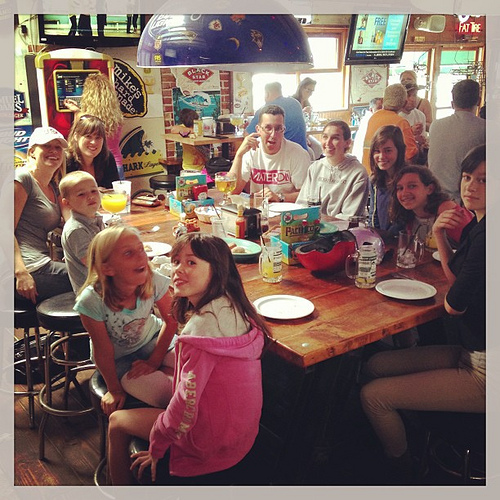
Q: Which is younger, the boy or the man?
A: The boy is younger than the man.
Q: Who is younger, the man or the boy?
A: The boy is younger than the man.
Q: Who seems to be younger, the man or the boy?
A: The boy is younger than the man.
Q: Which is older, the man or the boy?
A: The man is older than the boy.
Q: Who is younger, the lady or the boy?
A: The boy is younger than the lady.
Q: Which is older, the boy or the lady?
A: The lady is older than the boy.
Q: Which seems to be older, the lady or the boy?
A: The lady is older than the boy.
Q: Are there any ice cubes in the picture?
A: No, there are no ice cubes.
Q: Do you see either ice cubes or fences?
A: No, there are no ice cubes or fences.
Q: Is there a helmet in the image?
A: Yes, there is a helmet.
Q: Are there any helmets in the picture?
A: Yes, there is a helmet.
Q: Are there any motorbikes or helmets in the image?
A: Yes, there is a helmet.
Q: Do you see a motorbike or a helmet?
A: Yes, there is a helmet.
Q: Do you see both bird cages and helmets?
A: No, there is a helmet but no bird cages.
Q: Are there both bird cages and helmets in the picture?
A: No, there is a helmet but no bird cages.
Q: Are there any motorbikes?
A: No, there are no motorbikes.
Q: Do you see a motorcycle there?
A: No, there are no motorcycles.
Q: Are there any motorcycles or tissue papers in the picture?
A: No, there are no motorcycles or tissue papers.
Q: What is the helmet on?
A: The helmet is on the table.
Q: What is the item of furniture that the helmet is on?
A: The piece of furniture is a table.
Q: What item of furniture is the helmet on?
A: The helmet is on the table.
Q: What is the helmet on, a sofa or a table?
A: The helmet is on a table.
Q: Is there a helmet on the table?
A: Yes, there is a helmet on the table.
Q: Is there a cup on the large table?
A: No, there is a helmet on the table.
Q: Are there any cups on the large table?
A: No, there is a helmet on the table.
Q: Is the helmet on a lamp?
A: No, the helmet is on the table.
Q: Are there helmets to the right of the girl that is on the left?
A: Yes, there is a helmet to the right of the girl.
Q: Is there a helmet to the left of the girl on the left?
A: No, the helmet is to the right of the girl.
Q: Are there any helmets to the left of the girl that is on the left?
A: No, the helmet is to the right of the girl.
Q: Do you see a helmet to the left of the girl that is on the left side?
A: No, the helmet is to the right of the girl.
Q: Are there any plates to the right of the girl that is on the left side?
A: No, there is a helmet to the right of the girl.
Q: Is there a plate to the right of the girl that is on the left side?
A: No, there is a helmet to the right of the girl.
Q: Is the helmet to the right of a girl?
A: Yes, the helmet is to the right of a girl.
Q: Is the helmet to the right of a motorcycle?
A: No, the helmet is to the right of a girl.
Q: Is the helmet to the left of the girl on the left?
A: No, the helmet is to the right of the girl.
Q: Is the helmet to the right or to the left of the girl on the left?
A: The helmet is to the right of the girl.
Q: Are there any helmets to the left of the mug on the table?
A: Yes, there is a helmet to the left of the mug.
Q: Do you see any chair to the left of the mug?
A: No, there is a helmet to the left of the mug.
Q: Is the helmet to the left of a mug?
A: Yes, the helmet is to the left of a mug.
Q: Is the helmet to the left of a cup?
A: No, the helmet is to the left of a mug.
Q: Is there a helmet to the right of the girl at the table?
A: Yes, there is a helmet to the right of the girl.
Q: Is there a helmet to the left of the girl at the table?
A: No, the helmet is to the right of the girl.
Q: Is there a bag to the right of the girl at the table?
A: No, there is a helmet to the right of the girl.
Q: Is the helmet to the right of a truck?
A: No, the helmet is to the right of a girl.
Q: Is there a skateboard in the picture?
A: No, there are no skateboards.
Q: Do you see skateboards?
A: No, there are no skateboards.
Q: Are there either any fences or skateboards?
A: No, there are no skateboards or fences.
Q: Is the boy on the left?
A: Yes, the boy is on the left of the image.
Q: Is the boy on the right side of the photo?
A: No, the boy is on the left of the image.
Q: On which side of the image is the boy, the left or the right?
A: The boy is on the left of the image.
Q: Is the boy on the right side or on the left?
A: The boy is on the left of the image.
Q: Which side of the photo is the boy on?
A: The boy is on the left of the image.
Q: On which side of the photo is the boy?
A: The boy is on the left of the image.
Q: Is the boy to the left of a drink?
A: Yes, the boy is to the left of a drink.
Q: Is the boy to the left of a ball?
A: No, the boy is to the left of a drink.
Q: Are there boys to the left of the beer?
A: Yes, there is a boy to the left of the beer.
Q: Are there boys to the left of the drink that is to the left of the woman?
A: Yes, there is a boy to the left of the beer.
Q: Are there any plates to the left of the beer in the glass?
A: No, there is a boy to the left of the beer.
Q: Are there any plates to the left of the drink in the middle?
A: No, there is a boy to the left of the beer.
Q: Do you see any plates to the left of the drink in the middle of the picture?
A: No, there is a boy to the left of the beer.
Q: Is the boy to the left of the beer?
A: Yes, the boy is to the left of the beer.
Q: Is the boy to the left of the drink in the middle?
A: Yes, the boy is to the left of the beer.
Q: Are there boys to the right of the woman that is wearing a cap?
A: Yes, there is a boy to the right of the woman.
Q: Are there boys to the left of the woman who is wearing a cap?
A: No, the boy is to the right of the woman.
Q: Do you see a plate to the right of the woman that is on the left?
A: No, there is a boy to the right of the woman.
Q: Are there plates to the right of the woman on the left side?
A: No, there is a boy to the right of the woman.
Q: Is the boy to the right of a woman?
A: Yes, the boy is to the right of a woman.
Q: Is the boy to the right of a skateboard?
A: No, the boy is to the right of a woman.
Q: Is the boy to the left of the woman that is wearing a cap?
A: No, the boy is to the right of the woman.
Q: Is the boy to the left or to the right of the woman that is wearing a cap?
A: The boy is to the right of the woman.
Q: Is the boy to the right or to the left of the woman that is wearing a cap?
A: The boy is to the right of the woman.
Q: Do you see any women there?
A: Yes, there is a woman.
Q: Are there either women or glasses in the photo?
A: Yes, there is a woman.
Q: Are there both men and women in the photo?
A: Yes, there are both a woman and a man.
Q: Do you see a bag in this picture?
A: No, there are no bags.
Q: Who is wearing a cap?
A: The woman is wearing a cap.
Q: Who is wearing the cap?
A: The woman is wearing a cap.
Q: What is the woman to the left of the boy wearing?
A: The woman is wearing a cap.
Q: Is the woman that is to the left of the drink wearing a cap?
A: Yes, the woman is wearing a cap.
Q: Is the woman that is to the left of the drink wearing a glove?
A: No, the woman is wearing a cap.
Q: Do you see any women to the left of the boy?
A: Yes, there is a woman to the left of the boy.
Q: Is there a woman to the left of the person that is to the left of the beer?
A: Yes, there is a woman to the left of the boy.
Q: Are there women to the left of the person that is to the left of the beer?
A: Yes, there is a woman to the left of the boy.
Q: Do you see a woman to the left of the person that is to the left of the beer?
A: Yes, there is a woman to the left of the boy.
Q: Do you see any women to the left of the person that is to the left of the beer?
A: Yes, there is a woman to the left of the boy.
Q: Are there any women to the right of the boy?
A: No, the woman is to the left of the boy.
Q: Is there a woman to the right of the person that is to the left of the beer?
A: No, the woman is to the left of the boy.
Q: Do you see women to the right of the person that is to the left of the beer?
A: No, the woman is to the left of the boy.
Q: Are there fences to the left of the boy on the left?
A: No, there is a woman to the left of the boy.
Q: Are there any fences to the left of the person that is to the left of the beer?
A: No, there is a woman to the left of the boy.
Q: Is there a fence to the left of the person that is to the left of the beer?
A: No, there is a woman to the left of the boy.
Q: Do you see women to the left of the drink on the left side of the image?
A: Yes, there is a woman to the left of the drink.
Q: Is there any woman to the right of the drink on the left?
A: No, the woman is to the left of the drink.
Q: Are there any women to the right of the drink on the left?
A: No, the woman is to the left of the drink.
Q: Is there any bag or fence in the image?
A: No, there are no fences or bags.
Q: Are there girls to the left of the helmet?
A: Yes, there is a girl to the left of the helmet.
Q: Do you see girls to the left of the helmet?
A: Yes, there is a girl to the left of the helmet.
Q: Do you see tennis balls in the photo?
A: No, there are no tennis balls.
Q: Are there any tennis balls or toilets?
A: No, there are no tennis balls or toilets.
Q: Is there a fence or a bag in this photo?
A: No, there are no fences or bags.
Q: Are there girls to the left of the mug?
A: Yes, there is a girl to the left of the mug.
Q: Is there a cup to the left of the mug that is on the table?
A: No, there is a girl to the left of the mug.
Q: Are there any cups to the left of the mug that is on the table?
A: No, there is a girl to the left of the mug.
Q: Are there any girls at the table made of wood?
A: Yes, there is a girl at the table.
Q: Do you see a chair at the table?
A: No, there is a girl at the table.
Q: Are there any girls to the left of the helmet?
A: Yes, there is a girl to the left of the helmet.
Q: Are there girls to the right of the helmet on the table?
A: No, the girl is to the left of the helmet.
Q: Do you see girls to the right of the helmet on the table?
A: No, the girl is to the left of the helmet.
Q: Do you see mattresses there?
A: No, there are no mattresses.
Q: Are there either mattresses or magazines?
A: No, there are no mattresses or magazines.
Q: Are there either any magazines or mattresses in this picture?
A: No, there are no mattresses or magazines.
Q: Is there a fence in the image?
A: No, there are no fences.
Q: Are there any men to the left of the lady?
A: Yes, there is a man to the left of the lady.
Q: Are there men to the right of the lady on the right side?
A: No, the man is to the left of the lady.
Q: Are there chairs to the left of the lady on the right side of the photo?
A: No, there is a man to the left of the lady.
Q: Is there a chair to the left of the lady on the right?
A: No, there is a man to the left of the lady.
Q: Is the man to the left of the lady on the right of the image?
A: Yes, the man is to the left of the lady.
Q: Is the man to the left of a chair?
A: No, the man is to the left of the lady.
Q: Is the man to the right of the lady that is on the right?
A: No, the man is to the left of the lady.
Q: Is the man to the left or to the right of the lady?
A: The man is to the left of the lady.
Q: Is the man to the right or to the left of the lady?
A: The man is to the left of the lady.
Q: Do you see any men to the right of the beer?
A: Yes, there is a man to the right of the beer.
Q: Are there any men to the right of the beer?
A: Yes, there is a man to the right of the beer.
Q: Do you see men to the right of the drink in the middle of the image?
A: Yes, there is a man to the right of the beer.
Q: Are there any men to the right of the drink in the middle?
A: Yes, there is a man to the right of the beer.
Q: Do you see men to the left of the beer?
A: No, the man is to the right of the beer.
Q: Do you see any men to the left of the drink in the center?
A: No, the man is to the right of the beer.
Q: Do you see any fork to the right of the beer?
A: No, there is a man to the right of the beer.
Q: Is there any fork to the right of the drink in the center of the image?
A: No, there is a man to the right of the beer.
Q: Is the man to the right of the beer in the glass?
A: Yes, the man is to the right of the beer.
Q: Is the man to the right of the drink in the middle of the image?
A: Yes, the man is to the right of the beer.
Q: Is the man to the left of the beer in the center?
A: No, the man is to the right of the beer.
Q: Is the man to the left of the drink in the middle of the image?
A: No, the man is to the right of the beer.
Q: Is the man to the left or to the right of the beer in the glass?
A: The man is to the right of the beer.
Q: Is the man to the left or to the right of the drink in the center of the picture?
A: The man is to the right of the beer.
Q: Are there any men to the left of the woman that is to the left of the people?
A: Yes, there is a man to the left of the woman.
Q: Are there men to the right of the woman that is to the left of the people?
A: No, the man is to the left of the woman.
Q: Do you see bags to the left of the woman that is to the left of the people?
A: No, there is a man to the left of the woman.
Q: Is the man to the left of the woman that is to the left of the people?
A: Yes, the man is to the left of the woman.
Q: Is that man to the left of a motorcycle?
A: No, the man is to the left of the woman.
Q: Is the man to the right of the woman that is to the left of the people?
A: No, the man is to the left of the woman.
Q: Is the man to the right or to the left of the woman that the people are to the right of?
A: The man is to the left of the woman.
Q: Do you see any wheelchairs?
A: No, there are no wheelchairs.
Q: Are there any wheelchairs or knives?
A: No, there are no wheelchairs or knives.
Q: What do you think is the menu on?
A: The menu is on the table.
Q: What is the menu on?
A: The menu is on the table.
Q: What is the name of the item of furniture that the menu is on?
A: The piece of furniture is a table.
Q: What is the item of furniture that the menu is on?
A: The piece of furniture is a table.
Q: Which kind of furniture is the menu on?
A: The menu is on the table.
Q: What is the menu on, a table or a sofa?
A: The menu is on a table.